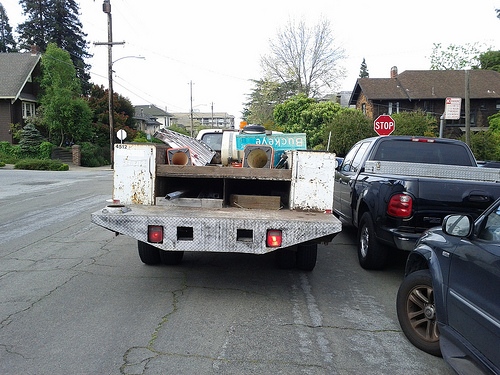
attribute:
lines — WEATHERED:
[287, 281, 334, 354]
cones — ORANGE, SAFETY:
[167, 146, 276, 172]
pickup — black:
[347, 121, 405, 219]